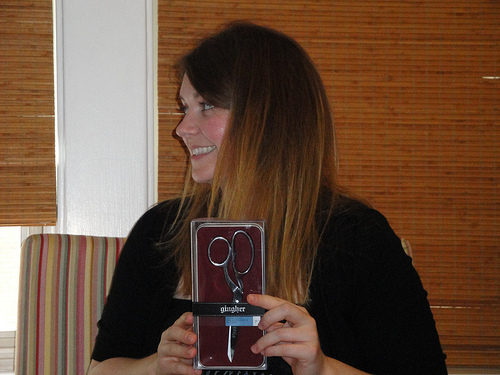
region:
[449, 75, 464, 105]
part of brown cover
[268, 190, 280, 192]
part of a woman's hair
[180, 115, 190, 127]
nose of a woman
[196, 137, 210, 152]
mouth of a woman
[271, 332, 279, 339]
finger of a woman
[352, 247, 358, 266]
part of a black shirt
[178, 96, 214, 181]
face of a woman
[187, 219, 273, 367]
scissors in a box.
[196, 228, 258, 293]
Handle to the scissors.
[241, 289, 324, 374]
Left hand on box.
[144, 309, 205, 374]
Right hand holds the box.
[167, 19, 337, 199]
A girl with a smile.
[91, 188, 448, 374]
A black tee shirt.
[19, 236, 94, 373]
A colorful seat cushion.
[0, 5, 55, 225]
Wodden blinds for the window.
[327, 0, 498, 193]
Wodden blinds for the window.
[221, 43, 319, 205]
The girl has brown hair.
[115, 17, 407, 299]
a women with blonde hair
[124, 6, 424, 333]
a women with long hair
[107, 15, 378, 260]
a women that is smiling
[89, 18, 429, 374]
a women wearing a black shirt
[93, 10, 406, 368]
a women wearing a black blouse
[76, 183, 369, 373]
a women holding a scissors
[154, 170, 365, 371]
scissors in an unopen case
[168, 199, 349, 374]
scissors in a case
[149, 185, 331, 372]
sharp scissors in a case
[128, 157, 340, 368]
silver scissors in a case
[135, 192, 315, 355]
the scissor is silver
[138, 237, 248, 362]
the scissor is silver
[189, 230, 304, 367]
the scissor is silver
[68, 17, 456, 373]
woman is smiling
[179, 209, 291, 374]
woman holds a scissors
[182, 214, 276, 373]
a scissor in a box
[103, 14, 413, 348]
person has long hair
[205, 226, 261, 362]
scissors are silver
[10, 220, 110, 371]
back of a chair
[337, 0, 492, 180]
Wall is brown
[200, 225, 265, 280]
handle of scissors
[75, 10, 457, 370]
man is wearing a black shirt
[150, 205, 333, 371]
hands holds a scissors